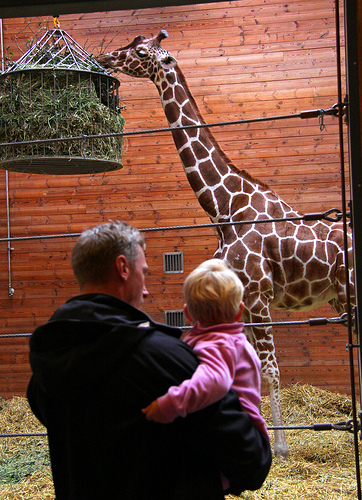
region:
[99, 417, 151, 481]
part of a sweater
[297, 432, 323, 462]
part of a stack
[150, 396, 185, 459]
edge of a sleeve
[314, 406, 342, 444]
part of a chain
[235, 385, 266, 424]
part of a sweater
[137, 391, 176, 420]
edge of a sleeve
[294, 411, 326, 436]
part of a chain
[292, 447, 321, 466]
part of a stack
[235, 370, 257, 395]
part of a sweater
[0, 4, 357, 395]
the wall is made of wood planks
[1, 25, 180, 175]
the giraffe is eating from a basket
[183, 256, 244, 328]
the child's hair is blond in color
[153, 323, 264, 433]
the toddler is wearing a pink jacket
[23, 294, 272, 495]
the man is wearing a black jacket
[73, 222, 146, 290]
the man's hair is greying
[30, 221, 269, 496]
the man is holding a toddler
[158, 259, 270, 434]
the toddler is looking at the giraffe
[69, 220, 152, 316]
the man is looking at the toddler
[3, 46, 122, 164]
the grass is green in color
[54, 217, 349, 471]
Man holding a baby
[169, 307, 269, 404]
Baby with pink shirt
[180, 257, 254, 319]
Baby with blond hair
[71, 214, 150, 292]
Man with grey hair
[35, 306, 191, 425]
Man with black jacket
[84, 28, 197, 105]
Giraffe eating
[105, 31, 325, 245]
Giraffe in front of a wall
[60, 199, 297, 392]
Man and baby looking at giraffe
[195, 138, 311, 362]
Giraffe in a pin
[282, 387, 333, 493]
Hay on the ground in a pin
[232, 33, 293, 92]
Large rusty brick wall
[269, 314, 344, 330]
Metal wire safety line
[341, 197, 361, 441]
Long metal safety rod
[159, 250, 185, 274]
Small grey metal vent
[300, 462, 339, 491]
Large amount of brown straw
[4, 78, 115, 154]
Shredded green grass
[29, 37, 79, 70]
Black metal feeder basket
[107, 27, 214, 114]
Tall giraffe eating grass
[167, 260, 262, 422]
Child wearing pink coat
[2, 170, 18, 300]
Long silver tone metal pipe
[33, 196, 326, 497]
a man holding a child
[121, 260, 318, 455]
child wearing a pink jacket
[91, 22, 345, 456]
this is a giraffe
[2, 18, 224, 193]
giraffe is eating hay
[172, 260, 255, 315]
blonde hair on the child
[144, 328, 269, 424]
a pink sweater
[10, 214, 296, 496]
a man holding a child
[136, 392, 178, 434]
the hand of a child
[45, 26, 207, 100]
a giraffe eating grass